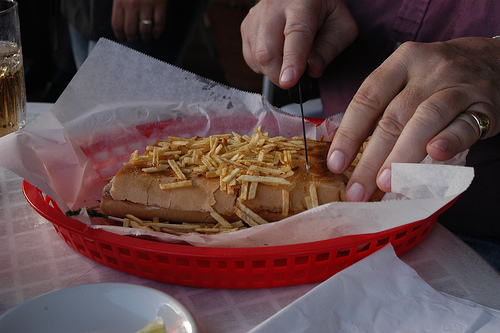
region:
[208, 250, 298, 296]
theb bowl is red in colour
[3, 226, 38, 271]
the table is covered with squares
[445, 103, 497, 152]
the little finger has a ring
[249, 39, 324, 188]
the woman is holding a knife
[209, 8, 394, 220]
the knife is cutting a burger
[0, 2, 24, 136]
the glass is half full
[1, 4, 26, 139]
there is brown liquid on the glass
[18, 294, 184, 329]
the bowl is white in colour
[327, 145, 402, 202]
the fingers are short and well trimmed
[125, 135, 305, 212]
the food is brown in colour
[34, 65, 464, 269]
food in a basket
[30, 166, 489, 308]
the basket is red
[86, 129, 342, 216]
fries on a sandwich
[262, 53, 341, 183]
a person is cutting the sandwich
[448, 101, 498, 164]
a ring on the finger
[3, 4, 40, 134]
beer in the background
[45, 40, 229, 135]
a white paper for the sandwich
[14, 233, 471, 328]
a white table beneath the sandwich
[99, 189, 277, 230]
the sandwich is fish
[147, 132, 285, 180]
the french fries are light brown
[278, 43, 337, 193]
THE PERSON IS HOLDING THE KNIFE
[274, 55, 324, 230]
THE PERSON IS CUTTING THE FOOD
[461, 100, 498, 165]
THE PERSON IS WEARING THE RING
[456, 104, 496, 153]
THE RING IS ON THE PERSONS PINKY FINGER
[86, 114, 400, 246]
THE FOOD IS ON THE PAPER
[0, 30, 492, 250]
THE PAPER IS WHITE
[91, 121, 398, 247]
THE FOOD IS IN THE BASKET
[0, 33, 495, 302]
THE PAPER IS IN THE BASKET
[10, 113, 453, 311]
THE BASKET IS PLASTIC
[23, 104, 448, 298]
THE BASKET IS RED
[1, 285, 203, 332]
A wish bowl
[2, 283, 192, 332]
A white bowl on the table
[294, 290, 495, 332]
A white napkin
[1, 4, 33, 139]
A clear glass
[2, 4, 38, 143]
A glass that is half full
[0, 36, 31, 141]
Liquid and ice in a glass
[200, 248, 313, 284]
Part of a red basket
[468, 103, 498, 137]
A gold ring on a pinkie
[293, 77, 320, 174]
A silver cutting knife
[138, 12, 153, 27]
A gold wedding band on a finger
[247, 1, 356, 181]
a hand with a knife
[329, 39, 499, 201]
a hand holding a sandwich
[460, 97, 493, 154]
a ring on a finger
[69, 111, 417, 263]
a sandwich in a basket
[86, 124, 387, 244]
a sandwich on a paper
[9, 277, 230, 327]
a round white bowl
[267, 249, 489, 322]
a paper napkin on a table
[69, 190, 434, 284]
a red basket on a table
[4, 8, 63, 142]
a glass of beer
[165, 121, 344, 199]
potatoe chips on a sandwich